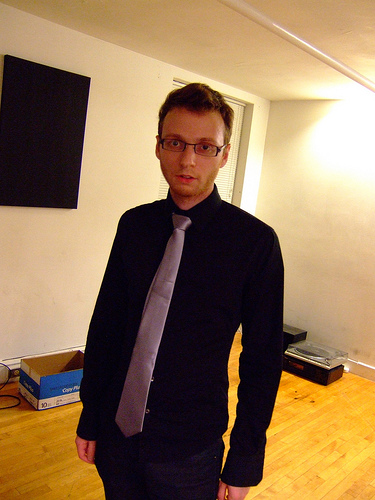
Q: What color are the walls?
A: White.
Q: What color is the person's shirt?
A: Black.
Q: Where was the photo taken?
A: Living Room.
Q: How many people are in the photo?
A: One.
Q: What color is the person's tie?
A: Purple.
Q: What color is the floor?
A: Light Brown.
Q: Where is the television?
A: To the left.